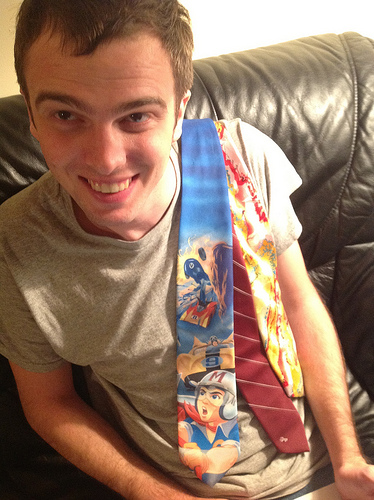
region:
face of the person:
[27, 22, 199, 324]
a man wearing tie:
[174, 346, 250, 452]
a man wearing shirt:
[36, 250, 354, 490]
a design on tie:
[184, 363, 239, 435]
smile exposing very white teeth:
[77, 174, 138, 202]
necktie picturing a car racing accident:
[172, 118, 241, 489]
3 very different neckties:
[168, 120, 307, 485]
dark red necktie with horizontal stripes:
[227, 211, 312, 456]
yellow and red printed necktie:
[215, 116, 311, 397]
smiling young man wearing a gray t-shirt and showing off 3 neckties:
[2, 2, 371, 497]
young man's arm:
[6, 346, 238, 498]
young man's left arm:
[273, 231, 370, 497]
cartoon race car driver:
[176, 369, 241, 480]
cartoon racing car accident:
[178, 238, 233, 339]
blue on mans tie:
[181, 329, 189, 341]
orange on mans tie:
[226, 344, 232, 365]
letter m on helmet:
[212, 370, 225, 382]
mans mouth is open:
[199, 408, 210, 415]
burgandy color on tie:
[247, 367, 263, 377]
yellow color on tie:
[272, 350, 276, 361]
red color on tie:
[277, 357, 285, 363]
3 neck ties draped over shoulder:
[177, 119, 311, 487]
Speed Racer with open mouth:
[179, 369, 242, 470]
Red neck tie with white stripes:
[232, 211, 309, 459]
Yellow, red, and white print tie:
[215, 122, 306, 398]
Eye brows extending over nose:
[34, 88, 169, 118]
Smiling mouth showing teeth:
[81, 172, 140, 202]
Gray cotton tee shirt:
[1, 170, 179, 473]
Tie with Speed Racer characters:
[175, 117, 241, 488]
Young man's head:
[15, 1, 195, 224]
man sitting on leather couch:
[5, 5, 372, 498]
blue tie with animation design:
[176, 113, 248, 494]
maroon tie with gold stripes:
[220, 213, 315, 461]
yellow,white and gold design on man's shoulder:
[210, 118, 312, 408]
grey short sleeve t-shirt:
[5, 110, 337, 486]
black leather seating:
[1, 23, 372, 493]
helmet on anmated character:
[183, 365, 238, 421]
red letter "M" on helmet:
[207, 369, 230, 385]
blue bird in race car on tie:
[177, 251, 222, 330]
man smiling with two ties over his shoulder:
[8, 1, 229, 235]